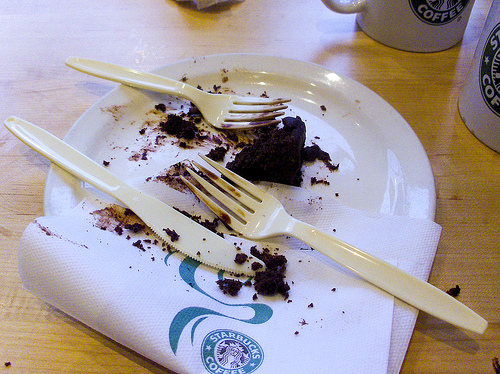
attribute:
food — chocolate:
[150, 93, 319, 292]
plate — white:
[42, 44, 444, 348]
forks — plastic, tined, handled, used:
[59, 50, 426, 261]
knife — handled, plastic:
[4, 113, 259, 288]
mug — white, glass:
[314, 2, 499, 152]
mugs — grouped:
[322, 1, 500, 164]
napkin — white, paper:
[20, 214, 421, 370]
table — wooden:
[2, 2, 497, 372]